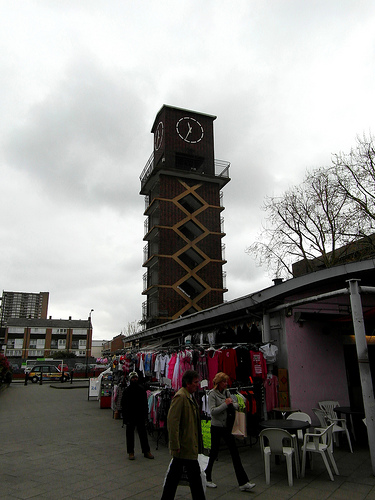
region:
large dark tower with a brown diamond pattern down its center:
[137, 101, 227, 321]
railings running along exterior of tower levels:
[136, 145, 226, 317]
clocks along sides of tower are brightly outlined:
[151, 111, 201, 147]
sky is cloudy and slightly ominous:
[1, 0, 372, 337]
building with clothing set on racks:
[108, 261, 373, 449]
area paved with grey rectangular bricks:
[1, 381, 374, 498]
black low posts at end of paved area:
[2, 370, 78, 393]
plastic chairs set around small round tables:
[257, 399, 360, 487]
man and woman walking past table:
[159, 371, 310, 497]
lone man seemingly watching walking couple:
[118, 370, 254, 498]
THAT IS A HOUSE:
[5, 316, 88, 350]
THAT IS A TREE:
[283, 210, 313, 257]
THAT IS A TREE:
[317, 179, 343, 251]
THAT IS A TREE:
[344, 168, 373, 218]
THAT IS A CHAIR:
[256, 421, 296, 479]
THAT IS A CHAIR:
[305, 417, 335, 476]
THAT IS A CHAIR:
[285, 409, 310, 440]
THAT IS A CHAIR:
[321, 397, 347, 433]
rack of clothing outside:
[105, 343, 264, 431]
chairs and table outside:
[262, 413, 346, 474]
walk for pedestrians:
[9, 386, 168, 485]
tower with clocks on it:
[138, 103, 234, 298]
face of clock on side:
[174, 113, 207, 146]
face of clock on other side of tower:
[142, 120, 163, 146]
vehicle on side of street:
[21, 365, 67, 382]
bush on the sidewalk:
[1, 369, 14, 386]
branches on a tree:
[241, 127, 361, 267]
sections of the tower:
[139, 183, 169, 317]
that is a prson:
[168, 373, 208, 497]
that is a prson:
[212, 374, 250, 487]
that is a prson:
[127, 368, 147, 459]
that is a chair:
[258, 423, 300, 487]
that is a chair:
[305, 416, 334, 484]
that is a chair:
[290, 405, 311, 435]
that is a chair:
[313, 392, 351, 429]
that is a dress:
[261, 341, 282, 369]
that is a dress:
[174, 346, 187, 386]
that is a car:
[27, 366, 63, 388]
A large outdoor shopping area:
[98, 324, 369, 478]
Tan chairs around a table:
[258, 425, 333, 473]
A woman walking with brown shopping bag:
[208, 363, 248, 486]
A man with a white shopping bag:
[146, 348, 207, 490]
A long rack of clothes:
[106, 348, 253, 418]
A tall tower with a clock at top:
[136, 93, 225, 316]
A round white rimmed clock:
[174, 111, 209, 149]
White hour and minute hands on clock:
[172, 112, 220, 153]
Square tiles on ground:
[12, 359, 92, 496]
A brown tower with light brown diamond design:
[143, 176, 226, 305]